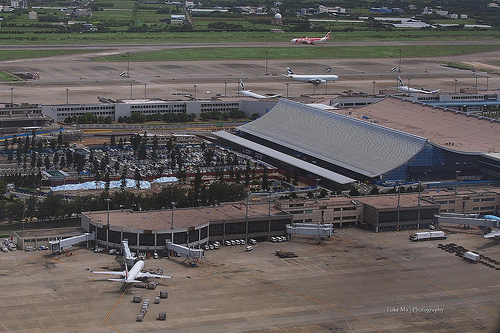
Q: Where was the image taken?
A: It was taken at the airport.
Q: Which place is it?
A: It is an airport.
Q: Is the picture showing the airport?
A: Yes, it is showing the airport.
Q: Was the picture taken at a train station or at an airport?
A: It was taken at an airport.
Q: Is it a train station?
A: No, it is an airport.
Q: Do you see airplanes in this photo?
A: Yes, there is an airplane.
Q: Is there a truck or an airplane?
A: Yes, there is an airplane.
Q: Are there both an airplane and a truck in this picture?
A: Yes, there are both an airplane and a truck.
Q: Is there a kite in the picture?
A: No, there are no kites.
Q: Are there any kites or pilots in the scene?
A: No, there are no kites or pilots.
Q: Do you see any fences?
A: No, there are no fences.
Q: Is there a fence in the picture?
A: No, there are no fences.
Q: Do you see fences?
A: No, there are no fences.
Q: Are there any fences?
A: No, there are no fences.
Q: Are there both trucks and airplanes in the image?
A: Yes, there are both an airplane and a truck.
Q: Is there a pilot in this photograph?
A: No, there are no pilots.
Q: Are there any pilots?
A: No, there are no pilots.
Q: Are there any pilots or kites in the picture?
A: No, there are no pilots or kites.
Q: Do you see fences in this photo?
A: No, there are no fences.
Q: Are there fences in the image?
A: No, there are no fences.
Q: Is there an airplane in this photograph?
A: Yes, there is an airplane.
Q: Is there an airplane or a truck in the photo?
A: Yes, there is an airplane.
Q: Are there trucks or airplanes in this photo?
A: Yes, there is an airplane.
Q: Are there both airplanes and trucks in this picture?
A: Yes, there are both an airplane and a truck.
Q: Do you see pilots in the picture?
A: No, there are no pilots.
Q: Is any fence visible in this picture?
A: No, there are no fences.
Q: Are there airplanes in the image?
A: Yes, there is an airplane.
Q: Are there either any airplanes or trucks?
A: Yes, there is an airplane.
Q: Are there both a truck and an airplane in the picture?
A: Yes, there are both an airplane and a truck.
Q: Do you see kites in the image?
A: No, there are no kites.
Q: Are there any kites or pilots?
A: No, there are no kites or pilots.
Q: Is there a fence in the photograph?
A: No, there are no fences.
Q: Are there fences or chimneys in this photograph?
A: No, there are no fences or chimneys.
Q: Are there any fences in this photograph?
A: No, there are no fences.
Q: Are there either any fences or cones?
A: No, there are no fences or cones.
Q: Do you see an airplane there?
A: Yes, there is an airplane.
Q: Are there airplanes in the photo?
A: Yes, there is an airplane.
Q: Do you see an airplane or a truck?
A: Yes, there is an airplane.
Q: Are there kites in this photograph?
A: No, there are no kites.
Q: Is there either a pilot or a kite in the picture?
A: No, there are no kites or pilots.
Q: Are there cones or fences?
A: No, there are no fences or cones.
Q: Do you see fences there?
A: No, there are no fences.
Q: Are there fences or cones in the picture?
A: No, there are no fences or cones.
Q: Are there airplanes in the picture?
A: Yes, there is an airplane.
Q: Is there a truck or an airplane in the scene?
A: Yes, there is an airplane.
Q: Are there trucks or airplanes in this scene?
A: Yes, there is an airplane.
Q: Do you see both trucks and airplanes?
A: Yes, there are both an airplane and a truck.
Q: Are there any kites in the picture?
A: No, there are no kites.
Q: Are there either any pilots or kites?
A: No, there are no kites or pilots.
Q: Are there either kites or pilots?
A: No, there are no kites or pilots.